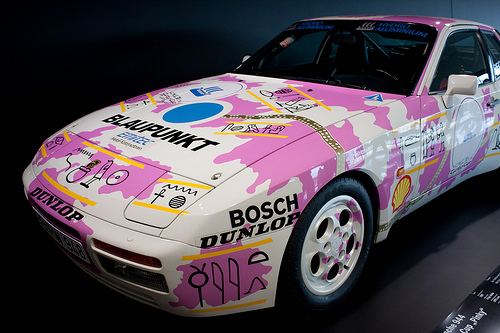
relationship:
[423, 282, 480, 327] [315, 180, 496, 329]
strip on floor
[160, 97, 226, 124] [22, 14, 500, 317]
circle on automobile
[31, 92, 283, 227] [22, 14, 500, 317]
symbols on automobile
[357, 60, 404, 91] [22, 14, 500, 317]
steering wheel on automobile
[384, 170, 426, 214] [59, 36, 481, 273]
logo on side of car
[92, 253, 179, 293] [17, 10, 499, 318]
headlight on automobile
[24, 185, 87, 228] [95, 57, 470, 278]
dunlop on car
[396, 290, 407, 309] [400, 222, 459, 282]
part of carpet